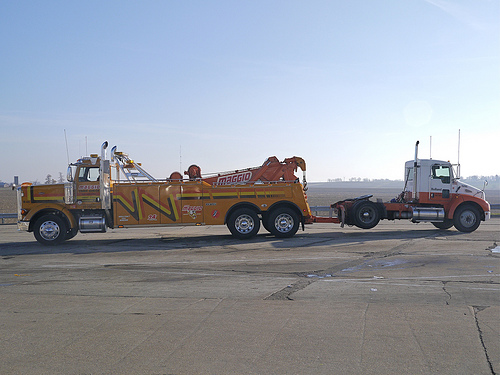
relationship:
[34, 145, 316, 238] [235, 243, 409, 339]
tow truck on road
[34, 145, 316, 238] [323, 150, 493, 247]
tow truck hauls cab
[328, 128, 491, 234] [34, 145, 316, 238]
cab hooked to tow truck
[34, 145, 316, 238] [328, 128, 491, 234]
tow truck hauls cab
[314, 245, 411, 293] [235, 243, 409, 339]
puddle on road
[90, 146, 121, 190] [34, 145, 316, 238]
pipes on tow truck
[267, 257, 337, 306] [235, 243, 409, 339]
crack in road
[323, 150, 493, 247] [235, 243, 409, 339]
truck on road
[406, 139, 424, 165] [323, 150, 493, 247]
exhaust on truck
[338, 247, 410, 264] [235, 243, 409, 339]
water on road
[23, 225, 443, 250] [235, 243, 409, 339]
shadows on road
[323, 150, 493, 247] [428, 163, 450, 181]
truck has window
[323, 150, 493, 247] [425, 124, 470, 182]
truck has antenna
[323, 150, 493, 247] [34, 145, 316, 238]
truck hooked to tow truck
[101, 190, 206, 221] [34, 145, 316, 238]
lines on tow truck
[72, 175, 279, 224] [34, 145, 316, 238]
stripes on tow truck